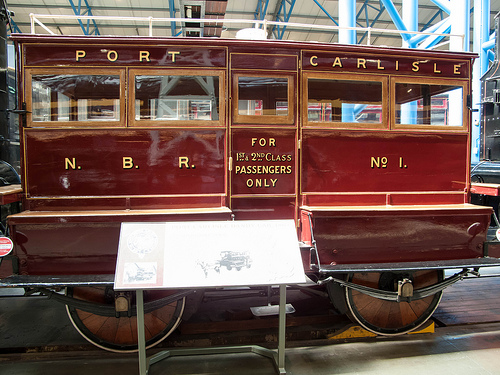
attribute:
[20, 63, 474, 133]
trim — wooden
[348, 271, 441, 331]
hub — wooden, brown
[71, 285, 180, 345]
hub — wooden, brown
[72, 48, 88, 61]
letter — gold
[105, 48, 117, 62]
letter — gold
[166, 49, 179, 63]
letter — gold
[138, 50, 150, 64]
letter — gold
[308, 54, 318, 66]
letter — gold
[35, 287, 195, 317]
brace — metal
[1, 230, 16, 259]
sign — red, white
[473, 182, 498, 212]
red cart —  little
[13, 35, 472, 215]
car — red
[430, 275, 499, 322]
floor — wooden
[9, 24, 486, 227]
train — bright red, clean, shiny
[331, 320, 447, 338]
wheel stops — yellow